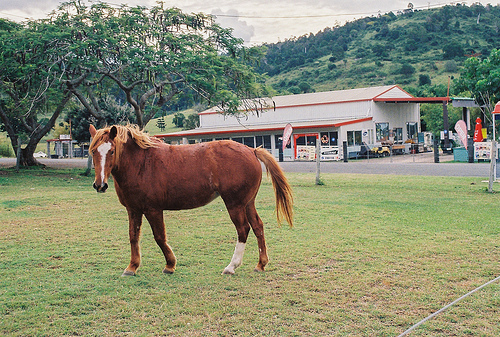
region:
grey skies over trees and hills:
[1, 1, 493, 76]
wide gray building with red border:
[160, 80, 450, 155]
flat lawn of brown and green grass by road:
[0, 151, 491, 326]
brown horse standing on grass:
[80, 120, 295, 281]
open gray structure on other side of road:
[22, 110, 83, 166]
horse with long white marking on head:
[86, 121, 116, 191]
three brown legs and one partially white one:
[120, 210, 270, 280]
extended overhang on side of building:
[360, 72, 470, 162]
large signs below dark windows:
[290, 125, 345, 160]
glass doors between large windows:
[373, 100, 419, 156]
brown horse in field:
[74, 114, 301, 284]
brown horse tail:
[252, 147, 307, 232]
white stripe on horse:
[90, 138, 114, 181]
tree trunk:
[7, 140, 42, 171]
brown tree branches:
[85, 63, 192, 96]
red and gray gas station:
[173, 80, 490, 171]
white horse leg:
[215, 233, 252, 278]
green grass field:
[2, 158, 496, 335]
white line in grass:
[400, 275, 497, 332]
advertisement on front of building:
[290, 140, 317, 161]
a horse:
[70, 110, 300, 275]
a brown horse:
[89, 118, 299, 268]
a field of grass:
[13, 189, 80, 307]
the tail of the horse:
[261, 150, 303, 224]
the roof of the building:
[305, 89, 337, 102]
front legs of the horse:
[123, 217, 178, 284]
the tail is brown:
[268, 167, 295, 219]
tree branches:
[113, 63, 145, 96]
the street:
[390, 162, 420, 174]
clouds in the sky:
[263, 14, 299, 33]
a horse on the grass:
[91, 125, 295, 271]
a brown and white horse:
[85, 113, 291, 282]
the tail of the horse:
[255, 140, 307, 225]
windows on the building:
[293, 134, 313, 146]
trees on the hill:
[365, 18, 443, 55]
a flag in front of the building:
[277, 128, 295, 147]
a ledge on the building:
[387, 84, 469, 105]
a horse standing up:
[83, 120, 295, 295]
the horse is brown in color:
[86, 121, 296, 279]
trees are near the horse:
[1, 5, 256, 175]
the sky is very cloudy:
[6, 2, 441, 49]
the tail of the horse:
[258, 147, 311, 226]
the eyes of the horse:
[86, 146, 117, 159]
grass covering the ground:
[10, 159, 491, 334]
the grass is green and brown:
[1, 163, 497, 326]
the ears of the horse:
[80, 121, 122, 138]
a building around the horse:
[188, 82, 485, 154]